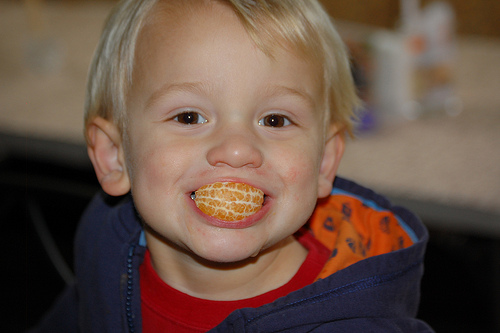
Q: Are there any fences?
A: No, there are no fences.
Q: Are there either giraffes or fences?
A: No, there are no fences or giraffes.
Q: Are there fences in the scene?
A: No, there are no fences.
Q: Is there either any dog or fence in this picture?
A: No, there are no fences or dogs.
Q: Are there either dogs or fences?
A: No, there are no fences or dogs.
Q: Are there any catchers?
A: No, there are no catchers.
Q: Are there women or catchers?
A: No, there are no catchers or women.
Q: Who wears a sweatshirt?
A: The boy wears a sweatshirt.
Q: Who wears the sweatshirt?
A: The boy wears a sweatshirt.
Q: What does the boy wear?
A: The boy wears a sweatshirt.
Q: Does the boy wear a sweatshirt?
A: Yes, the boy wears a sweatshirt.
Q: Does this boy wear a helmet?
A: No, the boy wears a sweatshirt.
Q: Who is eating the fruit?
A: The boy is eating the fruit.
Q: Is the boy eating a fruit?
A: Yes, the boy is eating a fruit.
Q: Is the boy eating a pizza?
A: No, the boy is eating a fruit.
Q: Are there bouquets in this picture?
A: No, there are no bouquets.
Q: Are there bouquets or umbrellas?
A: No, there are no bouquets or umbrellas.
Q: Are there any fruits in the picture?
A: Yes, there is a fruit.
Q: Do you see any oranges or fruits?
A: Yes, there is a fruit.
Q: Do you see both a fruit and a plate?
A: No, there is a fruit but no plates.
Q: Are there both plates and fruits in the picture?
A: No, there is a fruit but no plates.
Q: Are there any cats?
A: No, there are no cats.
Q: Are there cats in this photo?
A: No, there are no cats.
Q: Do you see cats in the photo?
A: No, there are no cats.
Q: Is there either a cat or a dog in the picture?
A: No, there are no cats or dogs.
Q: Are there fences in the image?
A: No, there are no fences.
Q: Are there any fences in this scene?
A: No, there are no fences.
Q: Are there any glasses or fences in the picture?
A: No, there are no fences or glasses.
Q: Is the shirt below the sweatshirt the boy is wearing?
A: Yes, the shirt is below the sweatshirt.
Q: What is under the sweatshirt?
A: The shirt is under the sweatshirt.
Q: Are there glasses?
A: No, there are no glasses.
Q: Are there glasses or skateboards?
A: No, there are no glasses or skateboards.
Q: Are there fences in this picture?
A: No, there are no fences.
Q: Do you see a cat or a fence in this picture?
A: No, there are no fences or cats.